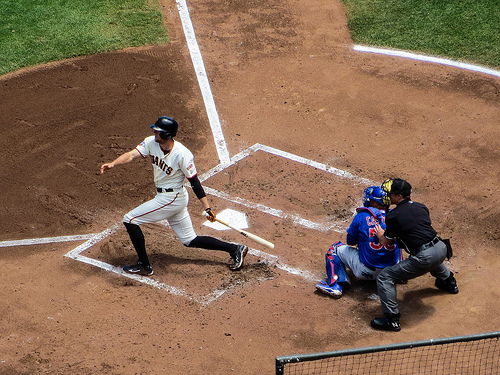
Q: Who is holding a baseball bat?
A: A man.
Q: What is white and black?
A: A baseball uniform.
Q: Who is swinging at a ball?
A: A baseball player.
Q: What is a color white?
A: A baseball uniform.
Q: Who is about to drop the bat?
A: A baseball player.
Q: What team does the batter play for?
A: The Giants.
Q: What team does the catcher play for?
A: The Cubs.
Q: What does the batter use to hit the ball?
A: A bat.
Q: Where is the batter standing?
A: A batter's box.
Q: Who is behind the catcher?
A: The umpire.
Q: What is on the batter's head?
A: A helmet.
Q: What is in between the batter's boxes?
A: Home Plate.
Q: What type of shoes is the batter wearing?
A: Cleats.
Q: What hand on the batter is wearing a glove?
A: Left.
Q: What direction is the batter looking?
A: Left field.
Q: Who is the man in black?
A: The umpire.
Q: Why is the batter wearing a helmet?
A: For safety.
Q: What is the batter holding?
A: A baseball bat.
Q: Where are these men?
A: On a baseball field.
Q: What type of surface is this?
A: Clay dirt.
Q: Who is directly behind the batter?
A: The catcher.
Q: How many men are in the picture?
A: Three.